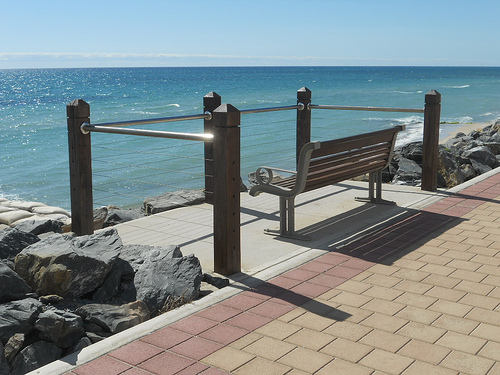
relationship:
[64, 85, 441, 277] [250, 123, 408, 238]
railing around bench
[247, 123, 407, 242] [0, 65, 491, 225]
bench near water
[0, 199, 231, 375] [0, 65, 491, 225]
rocks near water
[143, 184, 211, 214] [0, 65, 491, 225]
rocks near water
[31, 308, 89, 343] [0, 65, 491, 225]
rocks near water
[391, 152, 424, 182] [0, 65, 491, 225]
rocks near water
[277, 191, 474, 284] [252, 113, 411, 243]
shadow on bench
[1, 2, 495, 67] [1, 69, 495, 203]
blue sky above ocean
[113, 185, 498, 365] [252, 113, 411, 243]
walkway behind bench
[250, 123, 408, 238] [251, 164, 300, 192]
bench has armrest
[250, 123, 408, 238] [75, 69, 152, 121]
bench by water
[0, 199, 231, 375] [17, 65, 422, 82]
rocks around water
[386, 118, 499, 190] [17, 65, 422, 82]
rocks around water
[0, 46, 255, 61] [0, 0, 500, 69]
cloud on blue sky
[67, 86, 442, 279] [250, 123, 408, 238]
fence around bench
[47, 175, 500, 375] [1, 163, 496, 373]
brick on ground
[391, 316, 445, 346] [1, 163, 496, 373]
brick on ground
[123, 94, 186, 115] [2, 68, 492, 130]
waves in water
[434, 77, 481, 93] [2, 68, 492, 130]
waves in water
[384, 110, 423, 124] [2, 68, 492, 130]
waves in water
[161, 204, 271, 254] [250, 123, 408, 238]
cement under bench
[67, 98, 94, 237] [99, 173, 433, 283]
pole on concrete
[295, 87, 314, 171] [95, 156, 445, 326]
pole on concrete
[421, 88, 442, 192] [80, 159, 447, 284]
pole on concrete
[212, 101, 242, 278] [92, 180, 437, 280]
pole on concrete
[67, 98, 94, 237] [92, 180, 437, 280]
pole on concrete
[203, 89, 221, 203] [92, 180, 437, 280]
pole on concrete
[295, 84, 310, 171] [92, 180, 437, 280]
pole on concrete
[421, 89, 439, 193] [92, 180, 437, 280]
pole on concrete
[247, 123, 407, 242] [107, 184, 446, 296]
bench on concrete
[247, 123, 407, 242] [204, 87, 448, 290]
bench between poles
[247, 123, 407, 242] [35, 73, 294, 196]
bench facing water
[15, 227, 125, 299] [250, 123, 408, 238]
large rock near bench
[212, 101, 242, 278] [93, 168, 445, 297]
pole standing in concrete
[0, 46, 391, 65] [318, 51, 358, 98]
cloud in sky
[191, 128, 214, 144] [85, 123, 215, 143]
sun on metal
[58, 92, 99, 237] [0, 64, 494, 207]
pole near water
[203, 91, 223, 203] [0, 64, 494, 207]
pole near water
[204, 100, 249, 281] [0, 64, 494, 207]
pole near water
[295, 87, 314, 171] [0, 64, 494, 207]
pole near water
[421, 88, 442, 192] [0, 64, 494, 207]
pole near water